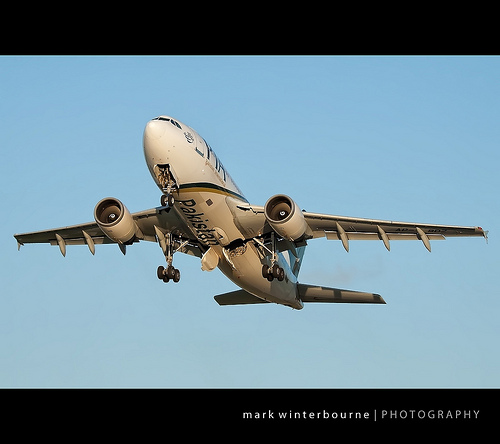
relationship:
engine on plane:
[86, 203, 139, 241] [14, 113, 490, 312]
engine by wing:
[255, 194, 309, 246] [248, 203, 493, 245]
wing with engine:
[248, 203, 493, 245] [255, 194, 309, 246]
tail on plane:
[226, 279, 399, 311] [14, 113, 490, 312]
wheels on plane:
[149, 260, 186, 288] [14, 113, 490, 312]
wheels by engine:
[149, 260, 186, 288] [86, 203, 139, 241]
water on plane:
[236, 408, 484, 421] [14, 113, 490, 312]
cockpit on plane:
[136, 110, 196, 158] [14, 113, 490, 312]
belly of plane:
[149, 189, 281, 265] [14, 113, 490, 312]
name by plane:
[236, 408, 484, 421] [14, 113, 490, 312]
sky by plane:
[264, 62, 480, 171] [14, 113, 490, 312]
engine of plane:
[86, 203, 139, 241] [14, 113, 490, 312]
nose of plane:
[139, 116, 161, 137] [14, 113, 490, 312]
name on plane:
[171, 195, 220, 250] [14, 113, 490, 312]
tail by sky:
[226, 279, 399, 311] [264, 62, 480, 171]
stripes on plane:
[172, 181, 249, 204] [14, 113, 490, 312]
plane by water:
[14, 113, 490, 312] [236, 408, 484, 421]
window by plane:
[156, 115, 185, 133] [14, 113, 490, 312]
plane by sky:
[14, 113, 490, 312] [264, 62, 480, 171]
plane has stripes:
[14, 113, 490, 312] [172, 181, 249, 204]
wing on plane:
[14, 211, 178, 249] [14, 113, 490, 312]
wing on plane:
[248, 203, 493, 245] [14, 113, 490, 312]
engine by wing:
[86, 203, 139, 241] [14, 211, 178, 249]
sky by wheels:
[264, 62, 480, 171] [149, 260, 186, 288]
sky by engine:
[264, 62, 480, 171] [86, 203, 139, 241]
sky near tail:
[264, 62, 480, 171] [226, 279, 399, 311]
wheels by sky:
[149, 260, 186, 288] [264, 62, 480, 171]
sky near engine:
[264, 62, 480, 171] [86, 203, 139, 241]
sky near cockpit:
[264, 62, 480, 171] [136, 110, 196, 158]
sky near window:
[264, 62, 480, 171] [156, 115, 185, 133]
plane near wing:
[14, 113, 490, 312] [248, 203, 493, 245]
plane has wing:
[14, 113, 490, 312] [248, 203, 493, 245]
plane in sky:
[14, 113, 490, 312] [264, 62, 480, 171]